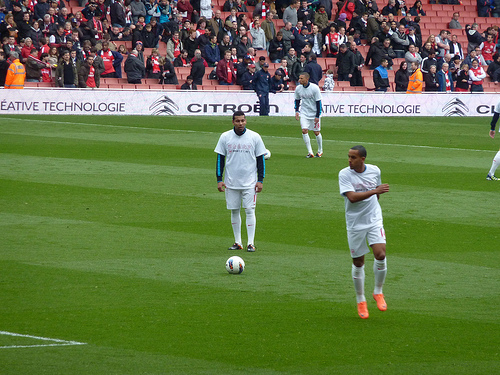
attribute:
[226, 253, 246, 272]
ball — white and black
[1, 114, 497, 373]
ground — green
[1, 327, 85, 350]
lines — white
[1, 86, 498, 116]
boundary board — white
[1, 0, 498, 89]
chairs — red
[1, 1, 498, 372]
stadium — full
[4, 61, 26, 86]
dress — orange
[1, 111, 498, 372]
soccer field — green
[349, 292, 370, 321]
cleat — orange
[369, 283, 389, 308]
cleat — orange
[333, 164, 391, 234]
uniform — white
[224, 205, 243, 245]
leg sleeve — white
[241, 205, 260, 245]
leg sleeve — white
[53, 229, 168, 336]
grass — green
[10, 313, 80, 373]
lines — white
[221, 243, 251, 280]
ball — white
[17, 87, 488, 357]
game area — fenced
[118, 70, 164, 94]
seats — red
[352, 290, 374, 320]
shoe — orange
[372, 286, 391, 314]
shoe — orange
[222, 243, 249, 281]
soccer ball — white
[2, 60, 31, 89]
coat — orange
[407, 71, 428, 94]
coat — orange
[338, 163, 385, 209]
shirt — white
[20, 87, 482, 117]
wall — short, white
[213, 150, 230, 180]
stripes — blue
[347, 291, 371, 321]
shoe — orange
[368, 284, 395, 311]
shoe — orange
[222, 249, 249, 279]
soccer ball — white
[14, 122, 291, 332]
grass — green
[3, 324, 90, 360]
lines — white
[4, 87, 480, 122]
field barrier — white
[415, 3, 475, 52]
chairs — brown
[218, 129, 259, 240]
uniform — white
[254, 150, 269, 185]
shirt sleeve — blue, black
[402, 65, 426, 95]
jacket — orange